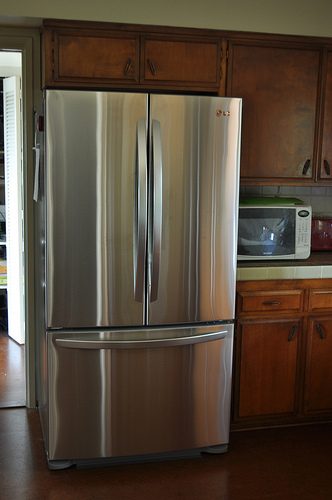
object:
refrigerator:
[33, 89, 243, 470]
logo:
[216, 109, 230, 117]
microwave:
[237, 197, 311, 261]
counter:
[230, 251, 332, 431]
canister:
[311, 219, 332, 250]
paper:
[32, 147, 40, 203]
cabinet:
[40, 18, 228, 96]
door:
[2, 74, 26, 345]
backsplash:
[239, 185, 332, 219]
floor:
[3, 471, 321, 499]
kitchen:
[0, 0, 331, 499]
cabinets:
[229, 277, 332, 432]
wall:
[0, 2, 332, 37]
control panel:
[296, 217, 309, 257]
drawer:
[237, 289, 305, 320]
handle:
[288, 326, 296, 342]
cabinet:
[225, 30, 331, 188]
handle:
[149, 118, 162, 302]